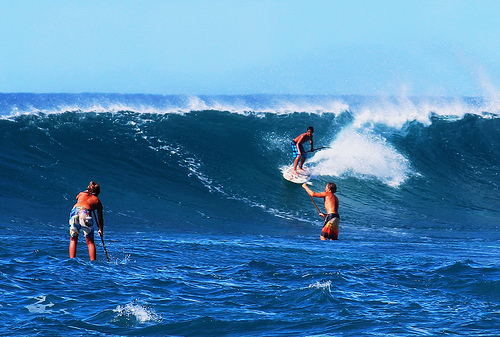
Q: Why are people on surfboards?
A: People are surfing.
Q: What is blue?
A: Sky.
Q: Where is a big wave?
A: In the ocean.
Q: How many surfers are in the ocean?
A: Three.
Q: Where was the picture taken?
A: At the beach.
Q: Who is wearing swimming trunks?
A: Three people.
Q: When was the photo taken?
A: Daytime.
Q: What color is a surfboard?
A: White.